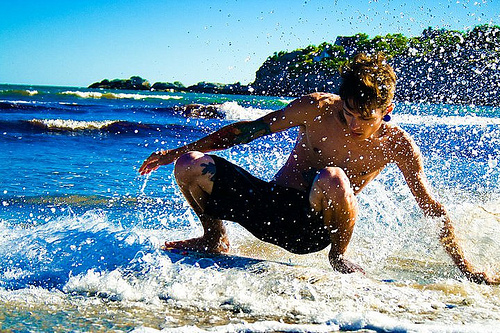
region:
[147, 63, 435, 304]
young surfer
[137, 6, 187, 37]
white clouds in blue sky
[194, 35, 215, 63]
white clouds in blue sky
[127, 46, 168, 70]
white clouds in blue sky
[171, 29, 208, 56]
white clouds in blue sky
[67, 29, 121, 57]
white clouds in blue sky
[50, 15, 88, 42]
white clouds in blue sky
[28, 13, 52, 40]
white clouds in blue sky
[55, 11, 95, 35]
white clouds in blue sky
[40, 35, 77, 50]
white clouds in blue sky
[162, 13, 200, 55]
white clouds in blue sky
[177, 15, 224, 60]
white clouds in blue sky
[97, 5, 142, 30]
white clouds in blue sky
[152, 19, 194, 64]
white clouds in blue sky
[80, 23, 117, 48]
white clouds in blue sky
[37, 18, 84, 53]
white clouds in blue sky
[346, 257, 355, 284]
There is a foot that is visible here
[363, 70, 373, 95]
This person has bright brown hair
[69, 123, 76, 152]
There is a very bright color of water here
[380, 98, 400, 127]
This person has an earring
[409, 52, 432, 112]
There are green trees in the background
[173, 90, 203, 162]
There are rocks in the background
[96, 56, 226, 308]
This photo is rather stunning here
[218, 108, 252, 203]
This man has brightly colored tattoos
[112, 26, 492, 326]
he is riding a skim board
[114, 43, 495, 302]
he is on the water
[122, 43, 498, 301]
he is on a skim board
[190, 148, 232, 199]
a tattoo on his thigh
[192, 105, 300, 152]
a tattoo on his arm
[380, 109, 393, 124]
a large blue gauge in his ear lobe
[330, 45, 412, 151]
he has stretched ear lobes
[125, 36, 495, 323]
he is wet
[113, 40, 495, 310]
he is not wearing a shirt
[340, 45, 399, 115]
he has brown hair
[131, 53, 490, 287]
This kids is wakeboarding.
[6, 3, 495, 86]
The sky is clear.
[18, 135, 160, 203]
The water is blue.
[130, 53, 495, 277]
The boy is shirtless.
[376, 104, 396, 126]
The boy's ear is pierced.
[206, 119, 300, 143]
The boy has a tattoo.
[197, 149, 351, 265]
The boy has black shorts.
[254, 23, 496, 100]
The trees are green.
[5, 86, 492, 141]
The waves are white.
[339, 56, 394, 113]
He has a full head of hair.